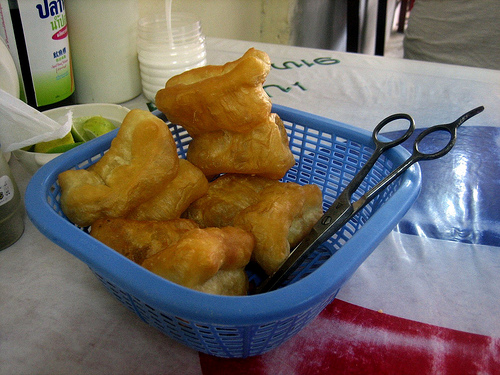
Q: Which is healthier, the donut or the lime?
A: The lime is healthier than the donut.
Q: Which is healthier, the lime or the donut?
A: The lime is healthier than the donut.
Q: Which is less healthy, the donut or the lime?
A: The donut is less healthy than the lime.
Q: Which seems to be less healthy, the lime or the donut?
A: The donut is less healthy than the lime.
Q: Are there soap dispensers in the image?
A: No, there are no soap dispensers.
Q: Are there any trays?
A: No, there are no trays.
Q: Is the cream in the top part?
A: Yes, the cream is in the top of the image.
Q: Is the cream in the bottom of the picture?
A: No, the cream is in the top of the image.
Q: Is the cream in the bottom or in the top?
A: The cream is in the top of the image.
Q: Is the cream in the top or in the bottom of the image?
A: The cream is in the top of the image.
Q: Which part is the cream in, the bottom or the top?
A: The cream is in the top of the image.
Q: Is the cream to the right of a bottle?
A: Yes, the cream is to the right of a bottle.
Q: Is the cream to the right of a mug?
A: No, the cream is to the right of a bottle.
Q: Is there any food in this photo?
A: Yes, there is food.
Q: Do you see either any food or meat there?
A: Yes, there is food.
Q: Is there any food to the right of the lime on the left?
A: Yes, there is food to the right of the lime.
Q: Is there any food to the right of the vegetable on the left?
A: Yes, there is food to the right of the lime.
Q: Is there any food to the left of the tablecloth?
A: Yes, there is food to the left of the tablecloth.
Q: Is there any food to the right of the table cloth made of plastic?
A: No, the food is to the left of the table cloth.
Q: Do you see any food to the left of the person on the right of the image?
A: Yes, there is food to the left of the person.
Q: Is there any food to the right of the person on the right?
A: No, the food is to the left of the person.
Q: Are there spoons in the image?
A: No, there are no spoons.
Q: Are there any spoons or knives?
A: No, there are no spoons or knives.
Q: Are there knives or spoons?
A: No, there are no spoons or knives.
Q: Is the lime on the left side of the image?
A: Yes, the lime is on the left of the image.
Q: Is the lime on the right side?
A: No, the lime is on the left of the image.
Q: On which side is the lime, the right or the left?
A: The lime is on the left of the image.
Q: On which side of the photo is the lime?
A: The lime is on the left of the image.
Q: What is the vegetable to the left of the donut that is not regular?
A: The vegetable is a lime.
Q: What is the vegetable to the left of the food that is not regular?
A: The vegetable is a lime.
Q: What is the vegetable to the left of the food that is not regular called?
A: The vegetable is a lime.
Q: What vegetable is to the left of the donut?
A: The vegetable is a lime.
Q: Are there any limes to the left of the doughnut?
A: Yes, there is a lime to the left of the doughnut.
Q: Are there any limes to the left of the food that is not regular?
A: Yes, there is a lime to the left of the doughnut.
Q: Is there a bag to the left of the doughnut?
A: No, there is a lime to the left of the doughnut.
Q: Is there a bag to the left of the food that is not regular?
A: No, there is a lime to the left of the doughnut.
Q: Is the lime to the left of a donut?
A: Yes, the lime is to the left of a donut.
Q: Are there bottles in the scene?
A: Yes, there is a bottle.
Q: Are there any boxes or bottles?
A: Yes, there is a bottle.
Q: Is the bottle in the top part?
A: Yes, the bottle is in the top of the image.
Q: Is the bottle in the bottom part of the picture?
A: No, the bottle is in the top of the image.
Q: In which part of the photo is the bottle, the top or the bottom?
A: The bottle is in the top of the image.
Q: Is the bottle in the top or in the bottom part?
A: The bottle is in the top of the image.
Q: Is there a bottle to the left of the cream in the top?
A: Yes, there is a bottle to the left of the cream.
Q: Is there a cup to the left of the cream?
A: No, there is a bottle to the left of the cream.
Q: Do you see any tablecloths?
A: Yes, there is a tablecloth.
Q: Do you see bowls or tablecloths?
A: Yes, there is a tablecloth.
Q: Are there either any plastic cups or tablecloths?
A: Yes, there is a plastic tablecloth.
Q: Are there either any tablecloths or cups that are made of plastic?
A: Yes, the tablecloth is made of plastic.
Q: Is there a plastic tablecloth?
A: Yes, there is a tablecloth that is made of plastic.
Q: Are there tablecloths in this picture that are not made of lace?
A: Yes, there is a tablecloth that is made of plastic.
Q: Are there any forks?
A: No, there are no forks.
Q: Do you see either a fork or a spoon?
A: No, there are no forks or spoons.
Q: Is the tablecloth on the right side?
A: Yes, the tablecloth is on the right of the image.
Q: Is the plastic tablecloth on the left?
A: No, the tablecloth is on the right of the image.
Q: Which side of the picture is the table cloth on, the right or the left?
A: The table cloth is on the right of the image.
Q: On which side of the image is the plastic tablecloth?
A: The table cloth is on the right of the image.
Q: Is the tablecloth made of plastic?
A: Yes, the tablecloth is made of plastic.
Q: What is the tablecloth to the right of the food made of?
A: The tablecloth is made of plastic.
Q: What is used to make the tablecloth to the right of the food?
A: The tablecloth is made of plastic.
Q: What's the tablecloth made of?
A: The tablecloth is made of plastic.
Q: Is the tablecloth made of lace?
A: No, the tablecloth is made of plastic.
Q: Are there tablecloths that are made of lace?
A: No, there is a tablecloth but it is made of plastic.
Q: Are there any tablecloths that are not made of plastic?
A: No, there is a tablecloth but it is made of plastic.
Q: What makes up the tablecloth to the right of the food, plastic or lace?
A: The tablecloth is made of plastic.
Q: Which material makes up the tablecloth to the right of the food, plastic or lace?
A: The tablecloth is made of plastic.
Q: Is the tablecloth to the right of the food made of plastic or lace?
A: The tablecloth is made of plastic.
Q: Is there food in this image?
A: Yes, there is food.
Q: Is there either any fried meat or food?
A: Yes, there is fried food.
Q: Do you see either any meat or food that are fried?
A: Yes, the food is fried.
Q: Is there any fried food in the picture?
A: Yes, there is fried food.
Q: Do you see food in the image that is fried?
A: Yes, there is food that is fried.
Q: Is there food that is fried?
A: Yes, there is food that is fried.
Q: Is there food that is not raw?
A: Yes, there is fried food.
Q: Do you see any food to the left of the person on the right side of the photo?
A: Yes, there is food to the left of the person.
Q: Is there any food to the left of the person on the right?
A: Yes, there is food to the left of the person.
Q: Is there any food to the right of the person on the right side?
A: No, the food is to the left of the person.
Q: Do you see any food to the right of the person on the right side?
A: No, the food is to the left of the person.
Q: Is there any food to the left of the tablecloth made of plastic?
A: Yes, there is food to the left of the tablecloth.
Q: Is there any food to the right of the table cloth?
A: No, the food is to the left of the table cloth.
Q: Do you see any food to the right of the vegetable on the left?
A: Yes, there is food to the right of the lime.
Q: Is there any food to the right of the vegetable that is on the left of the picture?
A: Yes, there is food to the right of the lime.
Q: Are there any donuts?
A: Yes, there is a donut.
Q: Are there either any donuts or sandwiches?
A: Yes, there is a donut.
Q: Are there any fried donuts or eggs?
A: Yes, there is a fried donut.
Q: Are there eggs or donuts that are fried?
A: Yes, the donut is fried.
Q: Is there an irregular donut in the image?
A: Yes, there is an irregular donut.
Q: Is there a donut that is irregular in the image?
A: Yes, there is an irregular donut.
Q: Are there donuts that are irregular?
A: Yes, there is a donut that is irregular.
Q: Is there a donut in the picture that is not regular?
A: Yes, there is a irregular donut.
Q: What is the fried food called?
A: The food is a donut.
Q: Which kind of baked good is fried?
A: The baked good is a donut.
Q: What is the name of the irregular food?
A: The food is a donut.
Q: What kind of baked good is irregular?
A: The baked good is a donut.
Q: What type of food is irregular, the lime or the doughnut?
A: The doughnut is irregular.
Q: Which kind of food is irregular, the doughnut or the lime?
A: The doughnut is irregular.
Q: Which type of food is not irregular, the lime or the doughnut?
A: The lime is not irregular.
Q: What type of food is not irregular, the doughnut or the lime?
A: The lime is not irregular.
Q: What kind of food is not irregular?
A: The food is a lime.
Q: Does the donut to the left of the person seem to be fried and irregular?
A: Yes, the donut is fried and irregular.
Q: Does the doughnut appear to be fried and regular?
A: No, the doughnut is fried but irregular.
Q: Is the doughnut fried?
A: Yes, the doughnut is fried.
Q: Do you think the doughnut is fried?
A: Yes, the doughnut is fried.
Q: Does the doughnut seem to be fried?
A: Yes, the doughnut is fried.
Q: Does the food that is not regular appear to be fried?
A: Yes, the doughnut is fried.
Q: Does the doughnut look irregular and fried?
A: Yes, the doughnut is irregular and fried.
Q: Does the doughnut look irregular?
A: Yes, the doughnut is irregular.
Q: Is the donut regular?
A: No, the donut is irregular.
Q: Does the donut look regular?
A: No, the donut is irregular.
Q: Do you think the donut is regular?
A: No, the donut is irregular.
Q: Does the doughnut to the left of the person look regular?
A: No, the doughnut is irregular.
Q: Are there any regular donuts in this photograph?
A: No, there is a donut but it is irregular.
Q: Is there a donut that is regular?
A: No, there is a donut but it is irregular.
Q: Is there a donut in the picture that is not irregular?
A: No, there is a donut but it is irregular.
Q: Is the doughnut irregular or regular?
A: The doughnut is irregular.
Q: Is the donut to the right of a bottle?
A: Yes, the donut is to the right of a bottle.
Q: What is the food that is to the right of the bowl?
A: The food is a donut.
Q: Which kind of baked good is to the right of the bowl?
A: The food is a donut.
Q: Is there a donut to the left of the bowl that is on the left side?
A: No, the donut is to the right of the bowl.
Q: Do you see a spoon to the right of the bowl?
A: No, there is a donut to the right of the bowl.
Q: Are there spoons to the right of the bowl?
A: No, there is a donut to the right of the bowl.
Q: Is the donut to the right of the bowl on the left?
A: Yes, the donut is to the right of the bowl.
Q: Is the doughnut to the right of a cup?
A: No, the doughnut is to the right of the bowl.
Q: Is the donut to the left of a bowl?
A: No, the donut is to the right of a bowl.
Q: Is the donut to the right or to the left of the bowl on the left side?
A: The donut is to the right of the bowl.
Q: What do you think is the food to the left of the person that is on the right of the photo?
A: The food is a donut.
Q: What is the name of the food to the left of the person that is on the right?
A: The food is a donut.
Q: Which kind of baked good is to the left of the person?
A: The food is a donut.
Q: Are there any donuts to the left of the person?
A: Yes, there is a donut to the left of the person.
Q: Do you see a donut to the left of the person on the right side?
A: Yes, there is a donut to the left of the person.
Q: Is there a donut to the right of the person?
A: No, the donut is to the left of the person.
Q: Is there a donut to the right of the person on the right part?
A: No, the donut is to the left of the person.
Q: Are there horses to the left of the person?
A: No, there is a donut to the left of the person.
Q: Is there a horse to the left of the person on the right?
A: No, there is a donut to the left of the person.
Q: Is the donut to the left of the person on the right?
A: Yes, the donut is to the left of the person.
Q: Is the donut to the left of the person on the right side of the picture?
A: Yes, the donut is to the left of the person.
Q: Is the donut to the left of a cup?
A: No, the donut is to the left of the person.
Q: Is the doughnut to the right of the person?
A: No, the doughnut is to the left of the person.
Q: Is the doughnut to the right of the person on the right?
A: No, the doughnut is to the left of the person.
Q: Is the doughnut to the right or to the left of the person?
A: The doughnut is to the left of the person.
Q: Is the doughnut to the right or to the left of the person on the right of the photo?
A: The doughnut is to the left of the person.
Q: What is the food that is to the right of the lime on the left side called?
A: The food is a donut.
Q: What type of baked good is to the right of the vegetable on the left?
A: The food is a donut.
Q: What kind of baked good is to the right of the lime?
A: The food is a donut.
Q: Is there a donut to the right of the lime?
A: Yes, there is a donut to the right of the lime.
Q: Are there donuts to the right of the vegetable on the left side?
A: Yes, there is a donut to the right of the lime.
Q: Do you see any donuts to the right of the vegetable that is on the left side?
A: Yes, there is a donut to the right of the lime.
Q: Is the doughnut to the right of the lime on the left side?
A: Yes, the doughnut is to the right of the lime.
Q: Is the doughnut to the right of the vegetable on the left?
A: Yes, the doughnut is to the right of the lime.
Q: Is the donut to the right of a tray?
A: No, the donut is to the right of the lime.